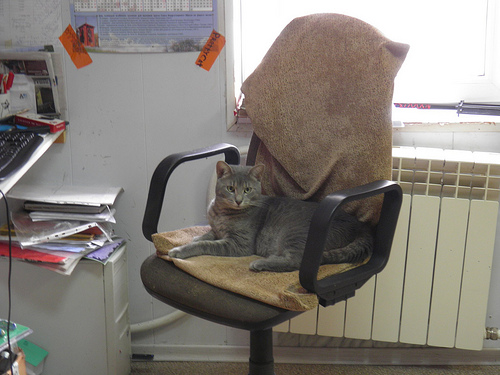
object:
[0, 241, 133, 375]
unit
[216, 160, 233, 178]
ear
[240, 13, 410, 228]
towel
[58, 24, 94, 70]
tape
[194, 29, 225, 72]
tape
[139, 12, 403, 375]
chair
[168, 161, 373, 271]
cat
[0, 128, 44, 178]
keyboard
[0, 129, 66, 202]
desk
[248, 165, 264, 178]
ears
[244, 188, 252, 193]
eye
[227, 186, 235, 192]
eye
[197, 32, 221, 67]
writing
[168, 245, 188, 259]
front paws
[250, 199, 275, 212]
whiskes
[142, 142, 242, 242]
arm rest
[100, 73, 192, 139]
wall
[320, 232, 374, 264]
tail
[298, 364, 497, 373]
floor